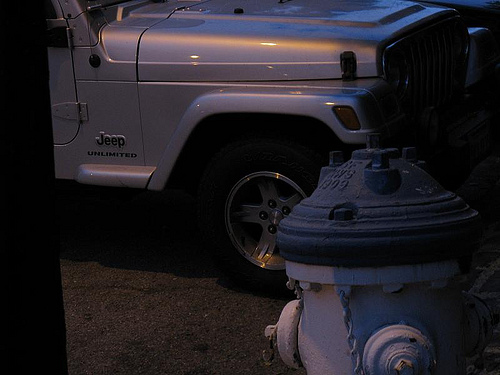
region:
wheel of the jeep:
[201, 139, 373, 344]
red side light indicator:
[325, 100, 374, 142]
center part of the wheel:
[243, 185, 290, 250]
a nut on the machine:
[265, 295, 286, 349]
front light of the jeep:
[366, 40, 418, 88]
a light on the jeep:
[170, 27, 362, 84]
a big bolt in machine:
[360, 325, 436, 373]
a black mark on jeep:
[81, 50, 102, 69]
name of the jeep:
[82, 122, 163, 177]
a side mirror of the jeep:
[16, 13, 76, 57]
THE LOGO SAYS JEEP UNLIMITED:
[80, 122, 147, 164]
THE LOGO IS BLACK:
[81, 126, 141, 167]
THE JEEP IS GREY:
[41, 0, 499, 304]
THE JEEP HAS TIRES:
[184, 130, 342, 315]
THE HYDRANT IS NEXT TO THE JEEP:
[256, 130, 499, 371]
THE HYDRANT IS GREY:
[253, 135, 499, 374]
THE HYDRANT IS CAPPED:
[253, 133, 498, 373]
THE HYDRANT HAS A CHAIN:
[328, 293, 368, 373]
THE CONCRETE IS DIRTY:
[54, 244, 311, 372]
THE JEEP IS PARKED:
[46, 4, 493, 294]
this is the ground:
[103, 275, 163, 344]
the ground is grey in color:
[83, 262, 168, 354]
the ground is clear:
[86, 275, 196, 350]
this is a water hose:
[278, 149, 490, 374]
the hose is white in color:
[305, 290, 330, 373]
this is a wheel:
[186, 147, 318, 287]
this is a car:
[63, 0, 435, 186]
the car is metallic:
[53, 7, 244, 179]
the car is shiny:
[203, 22, 240, 61]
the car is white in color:
[178, 31, 263, 58]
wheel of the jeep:
[198, 159, 309, 292]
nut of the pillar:
[346, 315, 438, 373]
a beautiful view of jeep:
[133, 16, 418, 247]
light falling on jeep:
[158, 25, 381, 78]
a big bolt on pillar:
[263, 315, 282, 349]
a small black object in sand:
[101, 297, 221, 362]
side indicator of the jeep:
[320, 97, 377, 138]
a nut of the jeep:
[328, 41, 370, 86]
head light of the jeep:
[371, 33, 423, 97]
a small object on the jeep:
[230, 2, 255, 23]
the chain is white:
[336, 314, 350, 332]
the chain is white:
[345, 330, 362, 356]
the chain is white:
[339, 323, 353, 340]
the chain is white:
[342, 320, 357, 346]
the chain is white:
[349, 336, 354, 350]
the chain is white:
[349, 329, 354, 339]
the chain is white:
[346, 328, 358, 346]